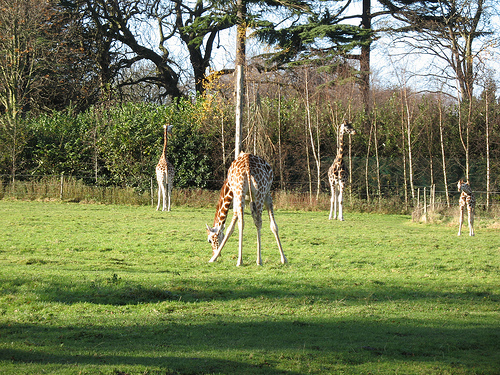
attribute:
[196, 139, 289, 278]
giraffe — brown, beige, grazing, bending, eating, bent over, spotted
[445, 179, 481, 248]
giraffe — small, baby, young, african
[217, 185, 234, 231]
neck — long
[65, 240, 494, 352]
grass — green, thick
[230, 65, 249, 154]
pole — white, large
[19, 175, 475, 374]
field — grass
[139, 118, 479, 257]
giraffes — fenced, eating, descent, african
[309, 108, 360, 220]
giraffe — large, standing, facing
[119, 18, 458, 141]
trees — tall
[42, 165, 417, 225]
fence — wired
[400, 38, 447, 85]
branch — twisted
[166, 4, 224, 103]
hedges — tall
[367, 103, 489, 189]
shrubs — tall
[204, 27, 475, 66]
skies — blue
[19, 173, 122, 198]
poles — wood